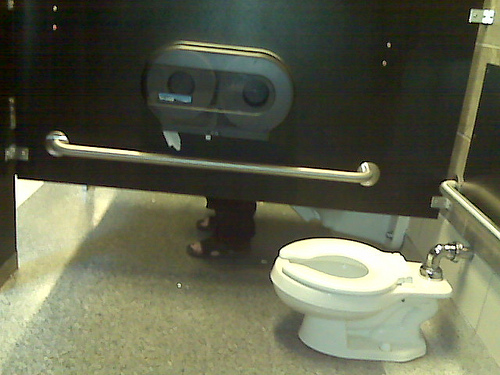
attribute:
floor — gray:
[99, 265, 208, 339]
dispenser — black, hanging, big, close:
[145, 46, 293, 158]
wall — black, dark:
[295, 16, 454, 155]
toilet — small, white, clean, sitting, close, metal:
[269, 228, 478, 367]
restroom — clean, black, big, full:
[9, 6, 483, 375]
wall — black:
[0, 0, 488, 273]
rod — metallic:
[39, 123, 379, 190]